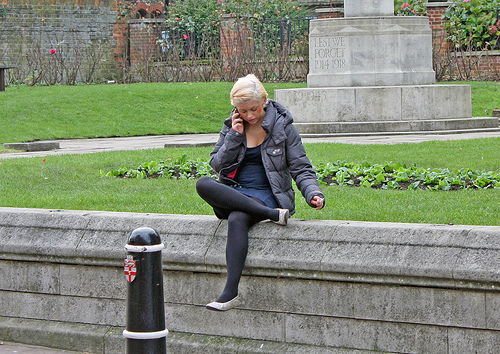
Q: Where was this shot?
A: Sidewalk.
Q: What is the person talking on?
A: Cell phone.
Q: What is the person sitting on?
A: Stone wall.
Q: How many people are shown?
A: 1.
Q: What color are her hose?
A: Black.